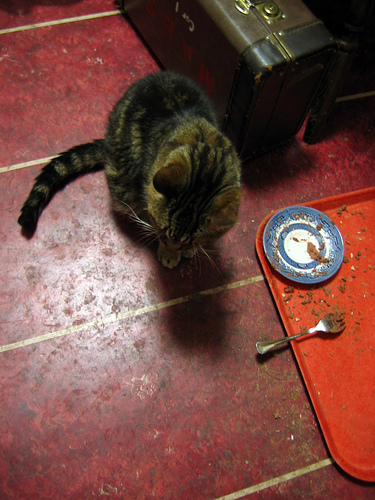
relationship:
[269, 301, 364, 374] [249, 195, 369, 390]
fork on tray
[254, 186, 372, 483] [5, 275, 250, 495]
orange tray on floor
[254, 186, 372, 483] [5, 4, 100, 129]
orange tray on floor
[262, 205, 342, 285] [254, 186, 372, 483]
saucer sitting on orange tray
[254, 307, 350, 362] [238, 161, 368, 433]
fork in a tray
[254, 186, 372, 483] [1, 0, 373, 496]
orange tray on floor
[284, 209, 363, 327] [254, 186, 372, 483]
cat food on orange tray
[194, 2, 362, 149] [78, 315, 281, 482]
suitcase on floor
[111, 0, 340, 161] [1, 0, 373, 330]
suitcase on floor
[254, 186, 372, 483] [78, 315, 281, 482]
orange tray on floor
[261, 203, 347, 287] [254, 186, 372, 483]
plate on orange tray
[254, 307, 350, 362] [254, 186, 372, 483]
fork on orange tray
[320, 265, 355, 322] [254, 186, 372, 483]
crumbs on orange tray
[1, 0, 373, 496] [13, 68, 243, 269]
floor under cat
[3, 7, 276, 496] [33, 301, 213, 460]
lines on floor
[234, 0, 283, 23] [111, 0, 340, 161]
lock on suitcase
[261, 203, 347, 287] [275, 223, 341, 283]
plate with blue decal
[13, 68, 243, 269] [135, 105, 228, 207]
cat with stripes